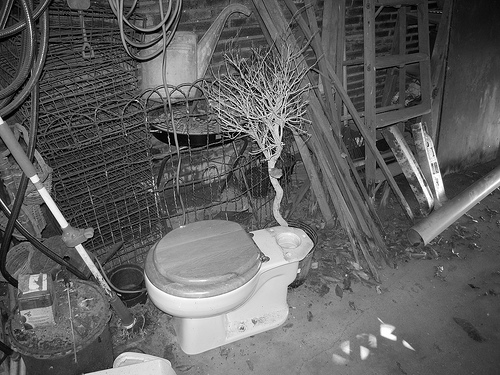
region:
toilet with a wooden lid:
[134, 215, 339, 358]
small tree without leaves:
[209, 41, 326, 223]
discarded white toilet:
[139, 216, 320, 361]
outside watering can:
[136, 2, 253, 117]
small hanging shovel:
[60, 0, 106, 68]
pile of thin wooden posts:
[249, 4, 432, 266]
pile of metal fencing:
[42, 40, 281, 260]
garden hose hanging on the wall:
[3, 2, 59, 245]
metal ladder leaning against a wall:
[331, 1, 451, 196]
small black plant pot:
[106, 262, 154, 304]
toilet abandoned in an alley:
[136, 210, 321, 360]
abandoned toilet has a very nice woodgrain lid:
[142, 205, 276, 322]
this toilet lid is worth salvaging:
[138, 210, 270, 311]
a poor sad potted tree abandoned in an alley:
[196, 9, 322, 292]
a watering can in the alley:
[126, 2, 259, 104]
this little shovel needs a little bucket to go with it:
[62, 1, 109, 63]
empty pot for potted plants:
[101, 257, 149, 312]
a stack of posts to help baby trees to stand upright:
[248, 0, 421, 287]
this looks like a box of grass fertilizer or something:
[12, 268, 65, 334]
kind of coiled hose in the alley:
[1, 0, 51, 297]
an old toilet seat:
[120, 199, 357, 369]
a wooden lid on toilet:
[146, 220, 278, 327]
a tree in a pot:
[196, 32, 362, 282]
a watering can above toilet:
[107, 8, 278, 127]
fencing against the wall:
[31, 82, 327, 246]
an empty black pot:
[93, 256, 169, 309]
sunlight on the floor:
[314, 307, 441, 366]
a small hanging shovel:
[60, 2, 112, 61]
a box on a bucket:
[14, 262, 77, 349]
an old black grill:
[138, 105, 261, 202]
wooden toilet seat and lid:
[141, 219, 261, 298]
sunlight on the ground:
[335, 316, 412, 364]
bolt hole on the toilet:
[237, 325, 246, 334]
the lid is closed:
[146, 220, 260, 291]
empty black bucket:
[106, 263, 144, 303]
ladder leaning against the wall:
[322, 0, 430, 196]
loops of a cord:
[109, 0, 181, 60]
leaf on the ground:
[334, 283, 342, 296]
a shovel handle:
[72, 10, 94, 59]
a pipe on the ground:
[409, 169, 499, 246]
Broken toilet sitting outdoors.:
[137, 210, 314, 354]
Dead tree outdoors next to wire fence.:
[196, 33, 325, 225]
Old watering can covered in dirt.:
[137, 1, 251, 96]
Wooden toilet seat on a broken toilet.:
[139, 217, 316, 354]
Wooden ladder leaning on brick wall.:
[329, 7, 446, 200]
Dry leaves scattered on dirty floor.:
[316, 219, 493, 354]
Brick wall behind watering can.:
[131, 0, 271, 96]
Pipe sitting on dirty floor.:
[394, 170, 499, 255]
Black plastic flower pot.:
[106, 261, 148, 305]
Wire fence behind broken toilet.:
[42, 71, 327, 271]